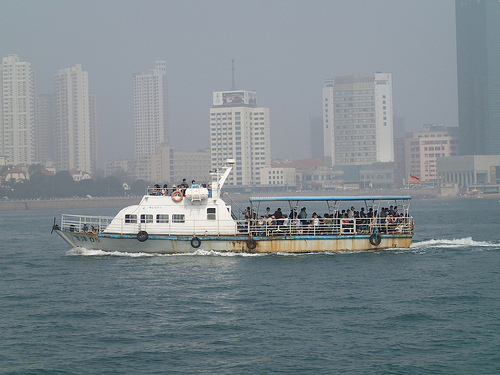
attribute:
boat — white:
[51, 157, 415, 252]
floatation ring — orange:
[170, 190, 182, 202]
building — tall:
[0, 52, 40, 169]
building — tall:
[55, 61, 99, 177]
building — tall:
[128, 52, 169, 185]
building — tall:
[208, 90, 272, 187]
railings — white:
[68, 209, 420, 238]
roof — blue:
[239, 182, 417, 209]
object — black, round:
[182, 231, 253, 283]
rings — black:
[128, 228, 393, 253]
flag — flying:
[406, 174, 419, 183]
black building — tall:
[455, 0, 490, 154]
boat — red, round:
[109, 142, 381, 282]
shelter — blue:
[247, 194, 413, 201]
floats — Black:
[126, 230, 268, 259]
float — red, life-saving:
[172, 187, 184, 199]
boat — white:
[52, 182, 412, 282]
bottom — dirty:
[233, 234, 414, 253]